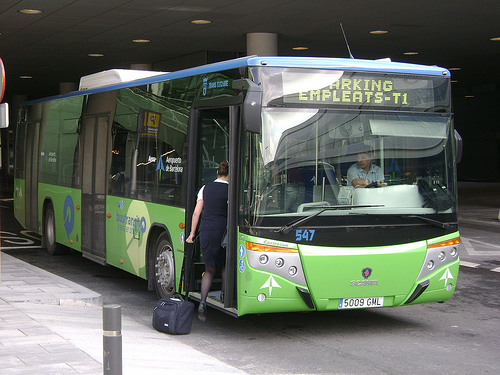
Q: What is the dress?
A: Blue.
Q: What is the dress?
A: Blue.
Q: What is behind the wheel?
A: The man.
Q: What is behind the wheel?
A: The man.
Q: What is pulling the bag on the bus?
A: The woman.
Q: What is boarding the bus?
A: The woman.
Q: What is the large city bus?
A: Green.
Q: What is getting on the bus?
A: The woman.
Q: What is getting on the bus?
A: The woman.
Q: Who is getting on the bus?
A: A woman in black.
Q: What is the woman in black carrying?
A: A suitcase.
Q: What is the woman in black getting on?
A: A green bus.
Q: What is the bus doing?
A: Picking up passengers.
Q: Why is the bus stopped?
A: To pick up passengers.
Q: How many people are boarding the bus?
A: 1.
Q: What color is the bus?
A: Green.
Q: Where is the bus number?
A: On the front of the bus.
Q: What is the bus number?
A: 547.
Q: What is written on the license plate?
A: 5009 GML.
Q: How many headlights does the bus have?
A: 6.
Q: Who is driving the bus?
A: The man.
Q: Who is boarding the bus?
A: A woman.